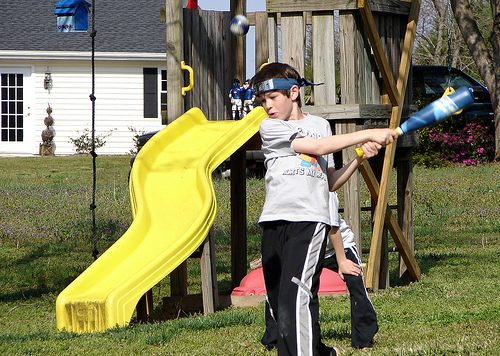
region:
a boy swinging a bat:
[213, 41, 494, 351]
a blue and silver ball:
[221, 10, 251, 40]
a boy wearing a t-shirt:
[236, 60, 346, 230]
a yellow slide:
[56, 85, 261, 346]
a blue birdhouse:
[42, 0, 103, 45]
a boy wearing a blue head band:
[241, 56, 311, 122]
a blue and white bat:
[345, 70, 475, 155]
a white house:
[2, 0, 183, 161]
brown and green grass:
[419, 170, 498, 352]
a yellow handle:
[176, 57, 196, 99]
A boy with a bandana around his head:
[237, 51, 360, 349]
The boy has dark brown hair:
[251, 54, 313, 124]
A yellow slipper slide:
[28, 102, 228, 352]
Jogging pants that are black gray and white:
[256, 189, 353, 354]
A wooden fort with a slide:
[153, 11, 390, 147]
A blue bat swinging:
[351, 75, 479, 160]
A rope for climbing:
[69, 1, 104, 253]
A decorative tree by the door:
[0, 87, 61, 180]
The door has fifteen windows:
[1, 72, 33, 155]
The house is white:
[1, 45, 122, 155]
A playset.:
[48, 0, 435, 337]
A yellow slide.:
[56, 107, 269, 337]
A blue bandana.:
[251, 78, 323, 93]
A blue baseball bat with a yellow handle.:
[350, 88, 475, 155]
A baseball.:
[225, 11, 254, 36]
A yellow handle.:
[181, 57, 193, 95]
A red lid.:
[231, 262, 349, 291]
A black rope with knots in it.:
[89, 1, 104, 259]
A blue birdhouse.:
[54, 1, 89, 35]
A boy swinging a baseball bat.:
[226, 7, 477, 352]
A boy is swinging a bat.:
[247, 61, 477, 192]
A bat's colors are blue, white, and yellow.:
[351, 81, 477, 161]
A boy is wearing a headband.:
[248, 65, 325, 122]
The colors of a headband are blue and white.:
[253, 72, 324, 118]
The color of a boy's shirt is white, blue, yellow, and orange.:
[255, 112, 342, 231]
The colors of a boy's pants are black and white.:
[256, 217, 339, 354]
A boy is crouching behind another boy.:
[259, 188, 379, 355]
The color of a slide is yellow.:
[55, 100, 272, 335]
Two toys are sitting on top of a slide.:
[222, 75, 257, 122]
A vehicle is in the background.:
[392, 63, 499, 165]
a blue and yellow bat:
[330, 83, 477, 156]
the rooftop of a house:
[3, 0, 170, 51]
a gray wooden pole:
[196, 242, 218, 314]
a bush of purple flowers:
[427, 117, 495, 171]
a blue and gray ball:
[227, 11, 252, 34]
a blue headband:
[255, 75, 302, 90]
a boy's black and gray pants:
[253, 210, 325, 355]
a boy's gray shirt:
[254, 117, 341, 226]